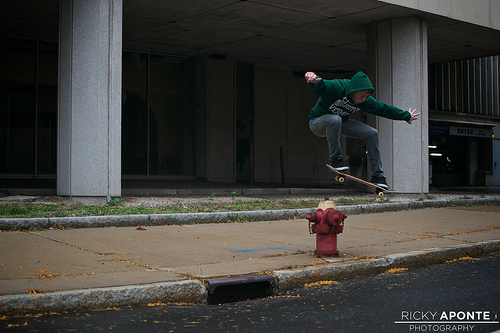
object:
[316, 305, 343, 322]
road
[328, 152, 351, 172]
shoe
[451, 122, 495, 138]
sign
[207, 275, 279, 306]
storm drain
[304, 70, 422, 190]
boy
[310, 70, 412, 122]
sweatshirt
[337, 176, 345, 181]
wheel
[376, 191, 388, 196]
wheel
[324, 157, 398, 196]
skateboard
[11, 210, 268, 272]
sidewalk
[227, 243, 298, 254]
paint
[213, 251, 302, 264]
line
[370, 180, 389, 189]
shoe